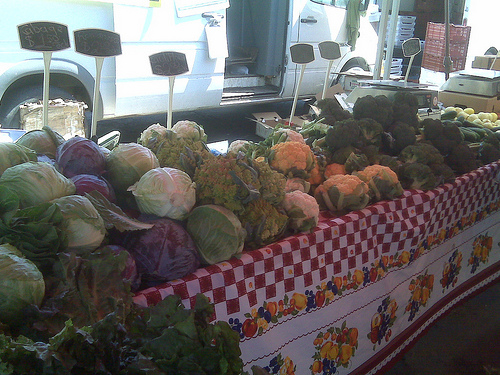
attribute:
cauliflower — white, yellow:
[311, 167, 375, 217]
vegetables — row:
[44, 110, 468, 240]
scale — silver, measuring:
[438, 70, 498, 98]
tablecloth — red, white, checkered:
[45, 161, 495, 373]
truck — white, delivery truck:
[4, 1, 390, 139]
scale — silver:
[438, 68, 499, 93]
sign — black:
[71, 29, 122, 56]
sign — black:
[146, 50, 187, 77]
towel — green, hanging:
[343, 1, 365, 48]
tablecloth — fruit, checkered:
[84, 154, 498, 366]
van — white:
[1, 0, 408, 132]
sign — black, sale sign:
[17, 19, 70, 53]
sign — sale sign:
[72, 27, 122, 62]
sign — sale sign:
[149, 49, 190, 79]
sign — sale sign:
[289, 44, 317, 64]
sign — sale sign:
[319, 40, 339, 62]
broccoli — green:
[350, 90, 396, 132]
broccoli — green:
[385, 85, 420, 127]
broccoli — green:
[320, 115, 384, 155]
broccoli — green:
[418, 106, 465, 153]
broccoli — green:
[398, 152, 437, 192]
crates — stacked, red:
[316, 44, 498, 194]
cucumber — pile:
[460, 126, 479, 141]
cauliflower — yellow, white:
[238, 131, 345, 216]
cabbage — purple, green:
[1, 128, 248, 332]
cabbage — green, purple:
[0, 126, 247, 371]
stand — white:
[41, 50, 53, 127]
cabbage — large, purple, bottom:
[134, 216, 196, 283]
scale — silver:
[432, 50, 498, 96]